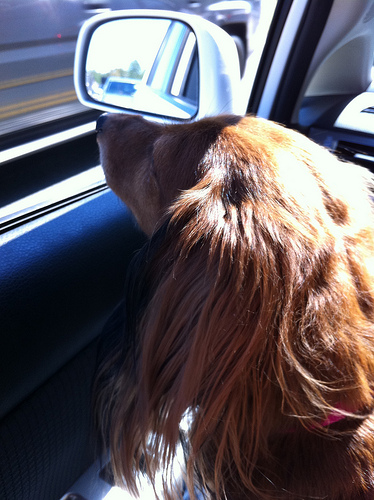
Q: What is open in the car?
A: The window.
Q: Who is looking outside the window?
A: The dog.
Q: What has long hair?
A: The dog.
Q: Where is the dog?
A: In a car.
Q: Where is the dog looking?
A: Outside the window.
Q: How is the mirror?
A: Concave.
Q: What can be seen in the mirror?
A: A vehicle.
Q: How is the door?
A: Closed.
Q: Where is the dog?
A: Inside of a car.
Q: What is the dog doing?
A: Smelling the air.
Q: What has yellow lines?
A: The roadway.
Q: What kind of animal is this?
A: A dog.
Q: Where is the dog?
A: In a car.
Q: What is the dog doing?
A: Looking out the window.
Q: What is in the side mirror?
A: A car.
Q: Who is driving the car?
A: The dog's owner.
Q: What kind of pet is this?
A: Dog.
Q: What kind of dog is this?
A: Dachshund.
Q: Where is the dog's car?
A: A street.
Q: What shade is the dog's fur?
A: Brown.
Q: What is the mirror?
A: The car side.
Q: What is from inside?
A: The car.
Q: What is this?
A: Dog.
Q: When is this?
A: Daytime.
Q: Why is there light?
A: Sun.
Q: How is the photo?
A: Clear.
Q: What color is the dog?
A: Brown.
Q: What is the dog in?
A: Car.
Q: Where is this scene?
A: In a car.